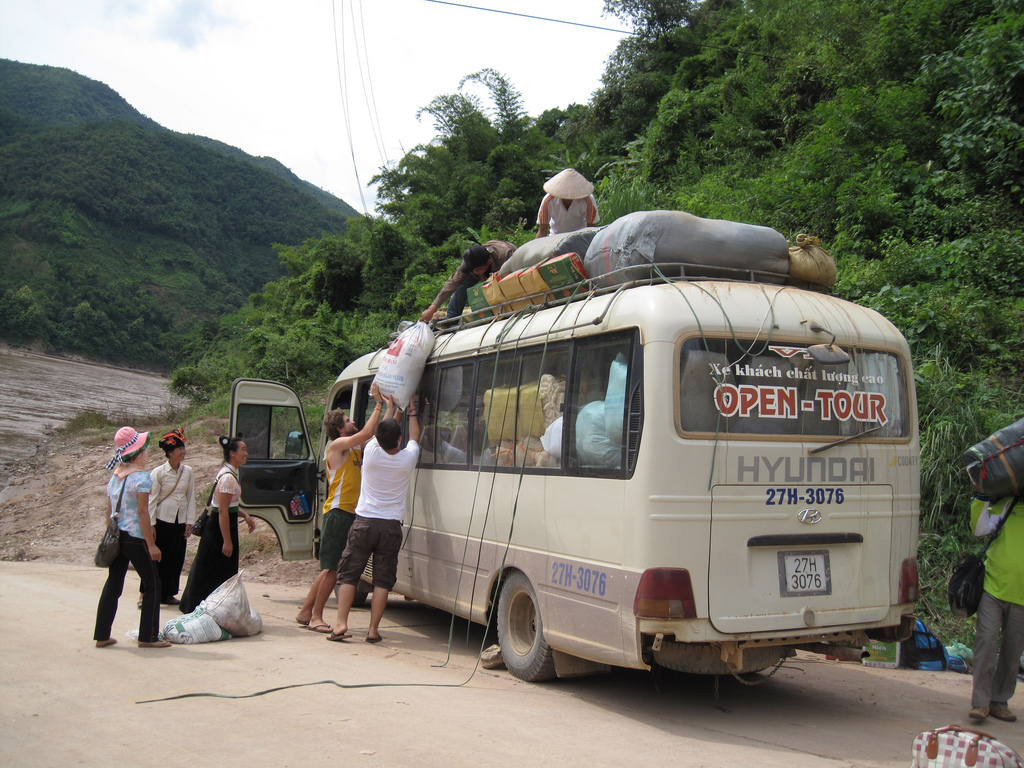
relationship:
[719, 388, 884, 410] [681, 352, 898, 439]
writing on window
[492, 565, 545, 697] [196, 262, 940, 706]
tire on bus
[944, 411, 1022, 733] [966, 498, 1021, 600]
person in shirt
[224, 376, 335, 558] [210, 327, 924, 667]
door on bus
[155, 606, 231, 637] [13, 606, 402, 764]
bag on ground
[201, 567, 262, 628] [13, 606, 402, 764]
bag on ground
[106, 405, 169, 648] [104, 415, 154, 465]
person in hat